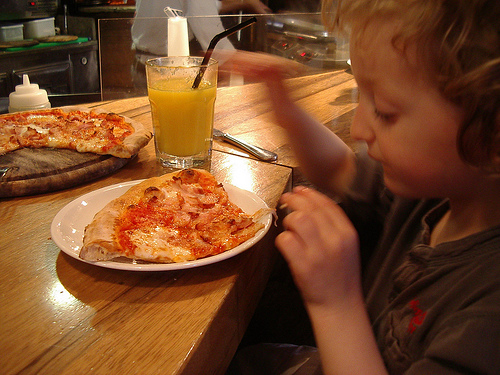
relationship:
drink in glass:
[146, 73, 217, 157] [142, 52, 224, 181]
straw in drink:
[193, 24, 257, 87] [146, 73, 217, 157]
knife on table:
[214, 127, 281, 178] [222, 77, 314, 194]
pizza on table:
[1, 111, 141, 166] [222, 77, 314, 194]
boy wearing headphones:
[217, 0, 500, 374] [472, 128, 497, 176]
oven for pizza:
[265, 16, 355, 59] [96, 170, 242, 256]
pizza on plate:
[96, 170, 242, 256] [67, 186, 96, 269]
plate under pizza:
[67, 186, 96, 269] [96, 170, 242, 256]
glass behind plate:
[142, 52, 224, 181] [67, 186, 96, 269]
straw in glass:
[193, 24, 257, 87] [142, 52, 224, 181]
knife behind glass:
[214, 127, 281, 178] [142, 52, 224, 181]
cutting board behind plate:
[5, 155, 114, 197] [67, 186, 96, 269]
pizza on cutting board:
[96, 170, 242, 256] [5, 155, 114, 197]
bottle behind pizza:
[15, 68, 57, 113] [1, 111, 141, 166]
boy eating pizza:
[217, 0, 500, 374] [96, 170, 242, 256]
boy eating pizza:
[273, 12, 500, 223] [96, 170, 242, 256]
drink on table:
[146, 73, 217, 157] [222, 77, 314, 194]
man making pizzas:
[139, 1, 250, 82] [1, 111, 141, 166]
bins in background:
[4, 21, 74, 42] [10, 9, 307, 70]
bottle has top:
[15, 68, 57, 113] [18, 72, 40, 90]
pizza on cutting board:
[1, 111, 141, 166] [5, 155, 114, 197]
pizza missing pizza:
[1, 111, 141, 166] [79, 169, 280, 269]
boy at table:
[273, 12, 500, 223] [222, 77, 314, 194]